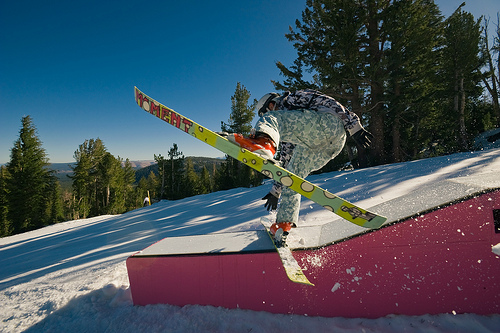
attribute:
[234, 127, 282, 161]
boots — ski, bright orange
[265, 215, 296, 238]
boots — ski, bright orange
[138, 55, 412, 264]
skier — falling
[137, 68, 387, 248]
man — performing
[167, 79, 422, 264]
man — performing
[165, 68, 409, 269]
man — skiing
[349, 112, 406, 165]
gloves — black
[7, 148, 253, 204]
trees — green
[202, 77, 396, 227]
skier — skiing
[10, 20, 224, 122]
sky — clear, blue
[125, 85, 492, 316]
trick — ski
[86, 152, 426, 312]
landscape — snowy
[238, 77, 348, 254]
person — colored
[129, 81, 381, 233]
skies — brightly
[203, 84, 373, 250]
skier — wearing orange boots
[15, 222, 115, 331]
snow — on the ground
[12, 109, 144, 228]
pine trees — on the mountain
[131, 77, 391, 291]
design — on the skis is funny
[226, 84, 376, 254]
skier — wearing camouflage clothing, wearing a helmet, lifting one leg in the air, wearing gloves, appears to be having trouble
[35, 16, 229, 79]
blue sky — crystal clear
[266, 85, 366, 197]
ski jacket — looks funny with those pants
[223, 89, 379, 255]
person — wearing orange ski boots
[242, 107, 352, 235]
skier's pants — camo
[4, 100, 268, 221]
evergreen trees — plentiful